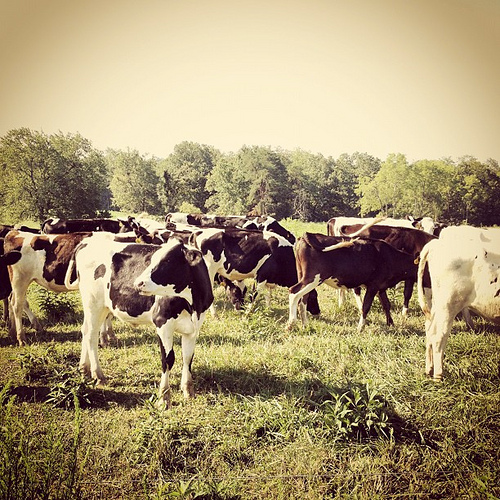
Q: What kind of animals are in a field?
A: Cows.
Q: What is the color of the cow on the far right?
A: White.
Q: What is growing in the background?
A: Trees.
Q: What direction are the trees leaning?
A: The left.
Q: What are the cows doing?
A: Grazing.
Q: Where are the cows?
A: In a field.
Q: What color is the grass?
A: Green.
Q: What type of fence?
A: Barbed wire.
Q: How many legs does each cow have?
A: 4.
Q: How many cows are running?
A: None.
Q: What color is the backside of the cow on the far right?
A: White.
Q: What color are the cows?
A: Brown and white.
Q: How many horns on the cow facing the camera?
A: Zero.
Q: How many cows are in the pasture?
A: 12.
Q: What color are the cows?
A: Black and white.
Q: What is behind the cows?
A: Trees.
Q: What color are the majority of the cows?
A: Black and white.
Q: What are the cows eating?
A: Grass.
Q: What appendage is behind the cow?
A: Tail.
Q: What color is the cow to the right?
A: White.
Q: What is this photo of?
A: Cows in a field.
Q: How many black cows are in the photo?
A: 1.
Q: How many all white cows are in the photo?
A: 2.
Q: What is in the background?
A: Trees.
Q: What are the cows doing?
A: Walking and grazing.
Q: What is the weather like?
A: Overcast.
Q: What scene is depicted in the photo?
A: A herd of cows grazing.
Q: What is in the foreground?
A: A patch of grass.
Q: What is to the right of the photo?
A: The white hind legs of a cow.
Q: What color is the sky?
A: Gray.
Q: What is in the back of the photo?
A: Trees.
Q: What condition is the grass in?
A: Long.